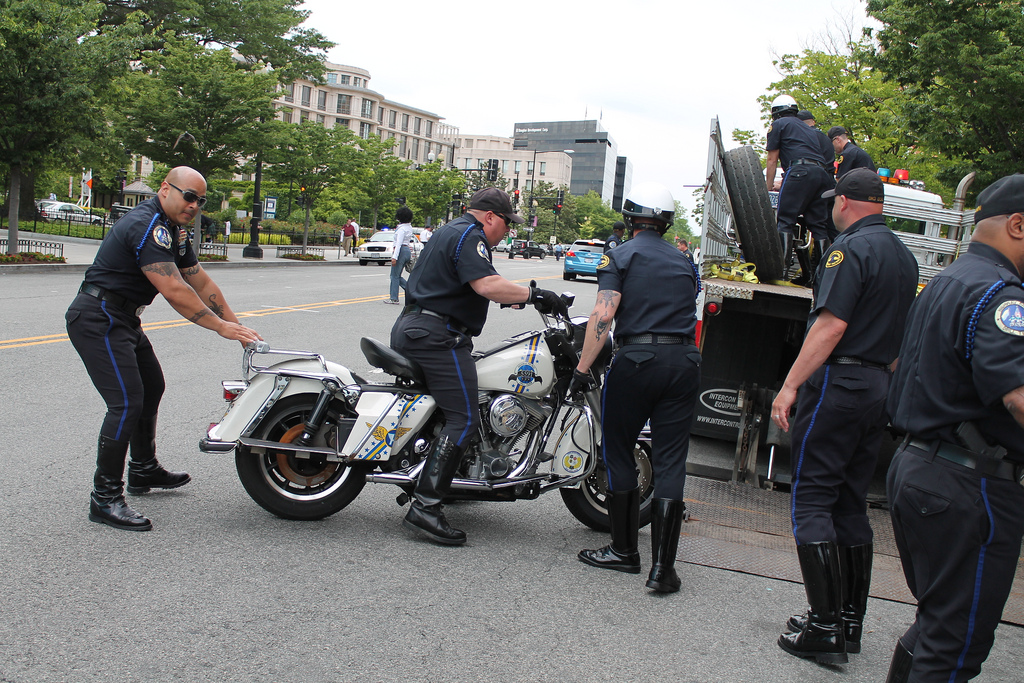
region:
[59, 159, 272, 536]
man wearing sunglasses holding motorcycle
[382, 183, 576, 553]
man in hat sitting on motorcycle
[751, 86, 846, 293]
man in blue pants standing in back of truck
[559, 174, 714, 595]
man in white helmet touching motorcycle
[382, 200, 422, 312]
woman in white shirt walking across street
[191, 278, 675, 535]
white motorcycle sitting on ground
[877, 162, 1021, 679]
man in blue shirt standing on street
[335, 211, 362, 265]
person in red shirt walking down sidewalk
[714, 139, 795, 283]
rubber tire sitting in back of truck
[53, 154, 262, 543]
cop behind a motorcycle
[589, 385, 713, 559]
the mans legs below torso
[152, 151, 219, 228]
the mans head above shoulders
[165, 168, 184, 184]
the hair on the mans head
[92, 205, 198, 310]
the mans shirt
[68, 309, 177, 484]
the mans pants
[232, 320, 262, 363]
the mans hand at end of arm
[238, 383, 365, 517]
the bikes rear wheel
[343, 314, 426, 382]
the bikes seat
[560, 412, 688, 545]
the bikes front wheel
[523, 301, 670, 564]
the front part of the bike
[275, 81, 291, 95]
glass window on the building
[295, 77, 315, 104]
glass window on the building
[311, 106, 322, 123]
glass window on the building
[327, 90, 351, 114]
glass window on the building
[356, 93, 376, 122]
glass window on the building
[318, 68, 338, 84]
glass window on the building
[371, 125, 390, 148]
glass window on the building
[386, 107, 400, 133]
glass window on the building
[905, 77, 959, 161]
green leaves on the tree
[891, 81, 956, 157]
green leaves on the tree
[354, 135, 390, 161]
green leaves on the tree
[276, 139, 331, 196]
green leaves on the tree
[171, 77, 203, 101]
green leaves on the tree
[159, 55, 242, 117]
green leaves on the tree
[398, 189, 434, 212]
green leaves on the tree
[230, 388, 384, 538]
A black rubber tire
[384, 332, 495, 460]
Blue stripe on black pants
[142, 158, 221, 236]
Man has a bald head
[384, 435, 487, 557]
A black rubber boot